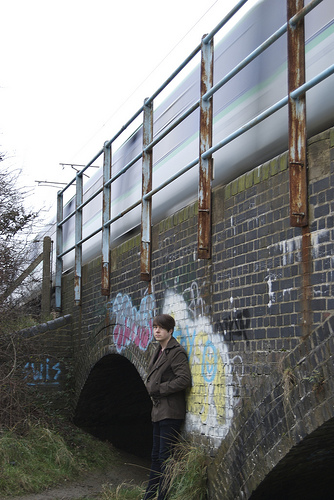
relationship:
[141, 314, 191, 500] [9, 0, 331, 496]
boy standing under bridge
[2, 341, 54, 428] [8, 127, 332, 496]
weeds growing on wall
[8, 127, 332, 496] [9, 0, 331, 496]
wall of bridge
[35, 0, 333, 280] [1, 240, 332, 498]
train on tracks of bridge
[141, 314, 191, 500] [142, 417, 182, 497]
boy wearing pants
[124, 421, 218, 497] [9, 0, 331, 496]
grass growing on side of bridge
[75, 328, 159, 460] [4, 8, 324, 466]
tunnel going under bridge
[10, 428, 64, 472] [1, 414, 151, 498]
grass growing on ground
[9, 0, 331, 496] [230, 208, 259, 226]
bridge made out of ciderblock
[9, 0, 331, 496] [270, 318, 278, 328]
bridge made out of ciderblock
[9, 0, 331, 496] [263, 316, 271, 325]
bridge made out of ciderblock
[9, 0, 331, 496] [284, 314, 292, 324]
bridge made out of ciderblock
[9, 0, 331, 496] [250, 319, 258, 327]
bridge made out of ciderblock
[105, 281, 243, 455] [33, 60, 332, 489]
graffiti on side of bridge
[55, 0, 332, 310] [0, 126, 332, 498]
guard rails on side of bridge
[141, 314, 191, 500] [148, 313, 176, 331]
boy with hair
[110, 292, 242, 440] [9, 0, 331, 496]
graffiti on side of bridge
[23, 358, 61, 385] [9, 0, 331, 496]
graffiti on side of bridge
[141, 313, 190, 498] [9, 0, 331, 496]
boy leaning on bridge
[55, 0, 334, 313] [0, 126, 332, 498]
guard rails along top of bridge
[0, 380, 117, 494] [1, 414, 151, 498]
grass on ground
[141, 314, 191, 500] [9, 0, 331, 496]
boy beside bridge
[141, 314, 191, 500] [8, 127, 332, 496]
boy on wall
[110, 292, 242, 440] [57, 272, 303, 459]
graffiti on wall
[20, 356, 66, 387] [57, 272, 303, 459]
graffiti on wall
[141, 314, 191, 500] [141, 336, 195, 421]
boy wears coat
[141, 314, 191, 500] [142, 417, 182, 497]
boy wears pants